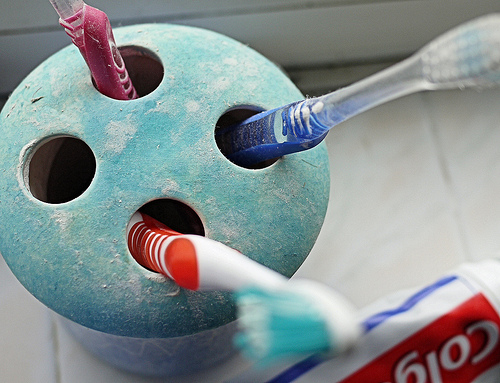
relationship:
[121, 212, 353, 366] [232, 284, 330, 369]
toothbrush with bristles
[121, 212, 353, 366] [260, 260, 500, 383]
toothbrush next to colgate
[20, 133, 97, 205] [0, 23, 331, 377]
holes in holder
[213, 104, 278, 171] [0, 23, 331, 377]
holes in holder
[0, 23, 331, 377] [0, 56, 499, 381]
holder on counter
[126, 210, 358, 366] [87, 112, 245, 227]
toothbrush on holder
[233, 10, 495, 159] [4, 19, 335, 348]
toothbrush on holder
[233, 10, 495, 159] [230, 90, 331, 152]
toothbrush has handle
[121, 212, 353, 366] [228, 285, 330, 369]
toothbrush with bristles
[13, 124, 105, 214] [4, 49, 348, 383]
hole in stand